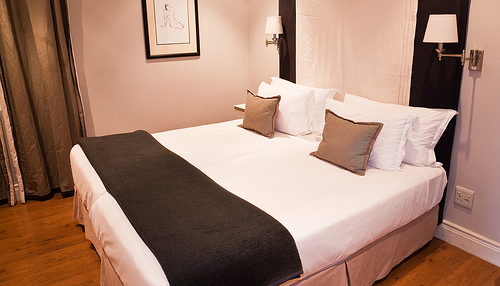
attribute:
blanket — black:
[80, 130, 305, 284]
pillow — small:
[310, 110, 380, 175]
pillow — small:
[238, 88, 281, 138]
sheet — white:
[236, 140, 304, 196]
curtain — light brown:
[0, 2, 84, 204]